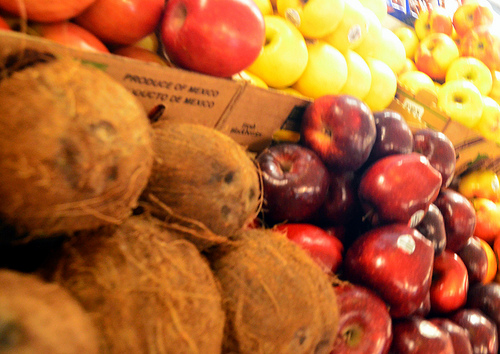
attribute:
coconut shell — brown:
[156, 121, 278, 248]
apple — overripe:
[251, 139, 338, 225]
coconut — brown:
[1, 60, 153, 241]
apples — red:
[246, 91, 499, 351]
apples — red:
[1, 0, 262, 76]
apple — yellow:
[455, 5, 495, 39]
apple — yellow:
[414, 11, 452, 39]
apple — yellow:
[416, 31, 458, 86]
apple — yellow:
[459, 28, 499, 71]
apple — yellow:
[443, 56, 492, 94]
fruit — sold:
[270, 110, 462, 345]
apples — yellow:
[257, 0, 417, 109]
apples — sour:
[437, 75, 485, 132]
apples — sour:
[445, 55, 496, 103]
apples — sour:
[475, 93, 497, 145]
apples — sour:
[413, 29, 460, 81]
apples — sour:
[452, 0, 494, 37]